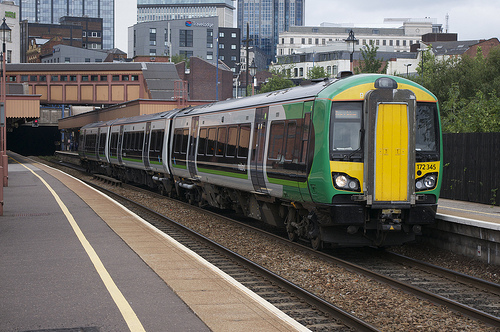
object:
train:
[82, 72, 439, 249]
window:
[331, 100, 365, 152]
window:
[416, 102, 439, 155]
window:
[269, 122, 286, 162]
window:
[237, 124, 254, 159]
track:
[21, 160, 380, 329]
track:
[59, 158, 499, 324]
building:
[128, 18, 219, 77]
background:
[5, 0, 499, 156]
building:
[62, 15, 104, 60]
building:
[271, 51, 353, 80]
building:
[0, 0, 22, 66]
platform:
[1, 148, 309, 330]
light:
[334, 176, 347, 187]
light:
[349, 182, 359, 192]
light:
[415, 182, 423, 190]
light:
[425, 174, 437, 187]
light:
[377, 77, 394, 89]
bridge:
[0, 64, 187, 103]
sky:
[3, 0, 499, 51]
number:
[416, 164, 437, 171]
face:
[331, 169, 440, 206]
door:
[376, 103, 408, 200]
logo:
[184, 21, 194, 27]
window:
[149, 28, 159, 48]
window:
[93, 29, 98, 40]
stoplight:
[33, 119, 40, 125]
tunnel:
[6, 125, 62, 156]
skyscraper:
[237, 0, 305, 69]